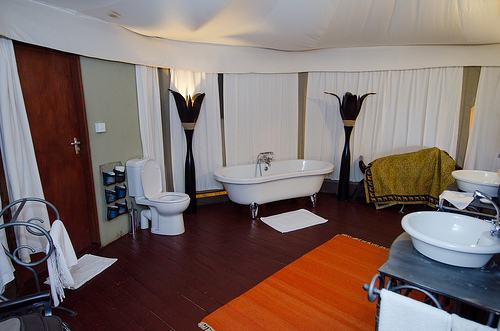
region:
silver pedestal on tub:
[243, 201, 260, 220]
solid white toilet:
[123, 155, 195, 240]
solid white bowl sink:
[401, 201, 496, 264]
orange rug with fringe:
[218, 251, 369, 327]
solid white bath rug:
[255, 209, 330, 233]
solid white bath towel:
[40, 220, 82, 302]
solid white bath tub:
[214, 163, 339, 202]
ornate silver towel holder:
[0, 201, 57, 284]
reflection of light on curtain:
[176, 73, 196, 95]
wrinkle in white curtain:
[417, 75, 431, 145]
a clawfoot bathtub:
[211, 121, 425, 254]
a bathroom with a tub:
[219, 133, 336, 220]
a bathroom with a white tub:
[223, 131, 321, 228]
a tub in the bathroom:
[239, 146, 354, 224]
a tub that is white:
[193, 114, 338, 257]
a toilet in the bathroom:
[109, 122, 211, 274]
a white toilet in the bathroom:
[129, 152, 201, 241]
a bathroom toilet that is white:
[107, 152, 184, 242]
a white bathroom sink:
[418, 167, 496, 295]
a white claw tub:
[210, 146, 332, 216]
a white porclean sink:
[400, 200, 495, 270]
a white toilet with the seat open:
[125, 150, 194, 250]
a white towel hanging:
[38, 207, 85, 308]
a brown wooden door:
[3, 35, 103, 267]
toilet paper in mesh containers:
[103, 155, 134, 222]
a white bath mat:
[258, 200, 335, 240]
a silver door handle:
[69, 137, 85, 156]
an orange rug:
[188, 216, 465, 326]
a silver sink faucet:
[471, 182, 496, 244]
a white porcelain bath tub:
[212, 157, 334, 217]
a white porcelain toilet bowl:
[135, 195, 191, 233]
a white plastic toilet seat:
[149, 190, 187, 202]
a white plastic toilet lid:
[141, 159, 165, 200]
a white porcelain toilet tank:
[126, 155, 146, 197]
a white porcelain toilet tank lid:
[126, 155, 148, 167]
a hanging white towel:
[44, 217, 76, 305]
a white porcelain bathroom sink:
[401, 207, 497, 267]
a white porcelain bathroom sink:
[449, 166, 499, 195]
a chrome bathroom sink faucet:
[473, 188, 499, 237]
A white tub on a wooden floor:
[213, 142, 340, 214]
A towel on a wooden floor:
[254, 203, 338, 235]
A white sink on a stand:
[366, 197, 499, 316]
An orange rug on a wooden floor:
[194, 230, 369, 329]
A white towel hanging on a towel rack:
[3, 199, 78, 307]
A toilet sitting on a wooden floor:
[124, 156, 195, 243]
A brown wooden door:
[13, 76, 100, 256]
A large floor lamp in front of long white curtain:
[168, 35, 225, 192]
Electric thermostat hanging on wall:
[92, 115, 115, 142]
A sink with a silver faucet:
[401, 180, 499, 281]